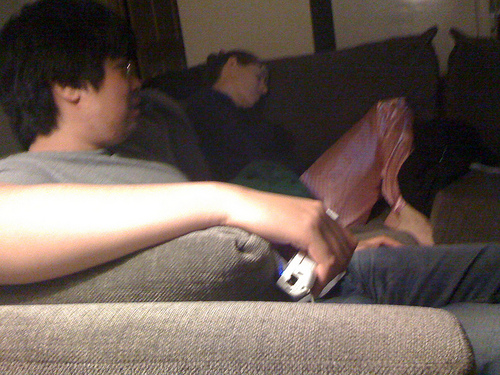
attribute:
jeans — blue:
[357, 247, 498, 350]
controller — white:
[258, 199, 351, 294]